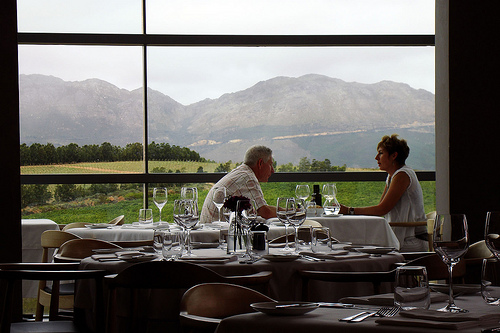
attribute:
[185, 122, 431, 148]
road — distant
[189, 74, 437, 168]
mountain — huge, distant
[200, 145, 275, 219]
man — hunched, talking, sitting, dining, eating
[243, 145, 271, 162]
hair — grey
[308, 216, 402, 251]
table — set, white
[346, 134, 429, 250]
woman — talking, sitting, dining, eating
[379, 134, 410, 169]
hair — brown, curly, short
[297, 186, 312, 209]
glass — tall, empty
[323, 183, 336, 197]
glass — tall, empty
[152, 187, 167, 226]
glass — tall, empty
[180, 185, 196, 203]
glass — tall, empty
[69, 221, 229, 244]
table — set, white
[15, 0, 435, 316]
window — very large, large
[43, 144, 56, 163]
tree — green, distant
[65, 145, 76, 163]
tree — green, distant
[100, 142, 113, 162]
tree — green, distant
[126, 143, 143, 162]
tree — green, distant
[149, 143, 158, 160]
tree — green, distant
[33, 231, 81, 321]
chair — round backed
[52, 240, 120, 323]
chair — round backed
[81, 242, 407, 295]
table — set, white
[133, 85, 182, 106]
mountain — huge, distant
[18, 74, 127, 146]
mountain — huge, distant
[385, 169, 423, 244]
shirt — white, sleeveless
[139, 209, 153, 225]
glass — upside-down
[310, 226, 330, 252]
glass — upside-down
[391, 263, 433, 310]
glass — upside-down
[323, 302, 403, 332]
silverware — set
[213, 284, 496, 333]
table — set, white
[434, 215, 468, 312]
glass — empty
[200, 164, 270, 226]
shirt — plaid, short-sleeved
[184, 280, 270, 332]
seat — empty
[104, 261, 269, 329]
seat — empty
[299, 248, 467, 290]
seat — empty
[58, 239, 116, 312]
seat — empty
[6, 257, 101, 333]
seat — empty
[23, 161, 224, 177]
crops — growing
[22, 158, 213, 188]
field — green